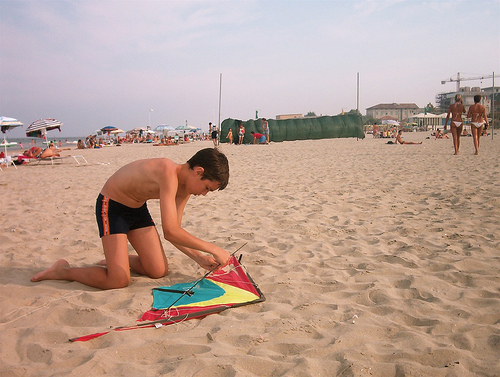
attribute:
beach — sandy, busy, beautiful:
[266, 168, 352, 193]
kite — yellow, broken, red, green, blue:
[205, 275, 241, 305]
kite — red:
[237, 271, 249, 286]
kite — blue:
[158, 292, 187, 303]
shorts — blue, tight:
[93, 202, 154, 228]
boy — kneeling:
[95, 233, 170, 288]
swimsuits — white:
[456, 106, 485, 125]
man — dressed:
[395, 128, 424, 151]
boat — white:
[9, 139, 18, 147]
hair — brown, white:
[195, 147, 221, 164]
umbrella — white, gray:
[8, 114, 26, 127]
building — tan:
[370, 96, 420, 117]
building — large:
[455, 74, 496, 100]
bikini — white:
[453, 112, 466, 116]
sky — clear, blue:
[132, 15, 388, 64]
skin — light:
[156, 173, 171, 188]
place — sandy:
[24, 114, 490, 341]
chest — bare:
[143, 184, 158, 199]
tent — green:
[274, 117, 366, 136]